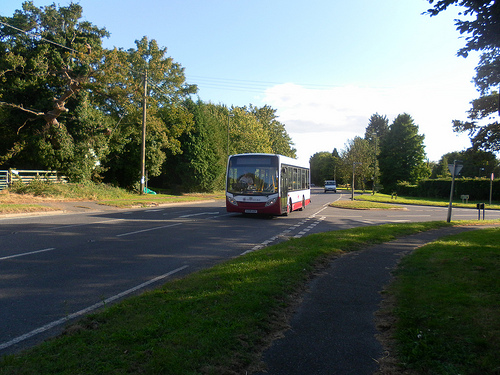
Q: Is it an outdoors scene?
A: Yes, it is outdoors.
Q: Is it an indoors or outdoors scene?
A: It is outdoors.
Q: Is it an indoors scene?
A: No, it is outdoors.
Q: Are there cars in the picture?
A: No, there are no cars.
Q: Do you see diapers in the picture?
A: No, there are no diapers.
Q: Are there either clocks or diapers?
A: No, there are no diapers or clocks.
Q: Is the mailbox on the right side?
A: Yes, the mailbox is on the right of the image.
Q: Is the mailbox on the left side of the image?
A: No, the mailbox is on the right of the image.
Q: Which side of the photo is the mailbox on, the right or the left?
A: The mailbox is on the right of the image.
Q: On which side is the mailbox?
A: The mailbox is on the right of the image.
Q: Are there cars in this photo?
A: No, there are no cars.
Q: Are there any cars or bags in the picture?
A: No, there are no cars or bags.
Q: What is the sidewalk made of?
A: The sidewalk is made of concrete.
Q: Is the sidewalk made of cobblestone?
A: No, the sidewalk is made of cement.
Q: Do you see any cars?
A: No, there are no cars.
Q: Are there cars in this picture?
A: No, there are no cars.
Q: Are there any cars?
A: No, there are no cars.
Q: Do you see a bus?
A: Yes, there is a bus.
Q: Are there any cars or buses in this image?
A: Yes, there is a bus.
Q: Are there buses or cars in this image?
A: Yes, there is a bus.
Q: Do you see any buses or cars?
A: Yes, there is a bus.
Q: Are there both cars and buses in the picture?
A: No, there is a bus but no cars.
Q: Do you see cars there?
A: No, there are no cars.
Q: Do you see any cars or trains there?
A: No, there are no cars or trains.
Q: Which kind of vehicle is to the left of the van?
A: The vehicle is a bus.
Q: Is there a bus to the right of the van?
A: No, the bus is to the left of the van.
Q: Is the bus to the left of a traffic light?
A: No, the bus is to the left of a van.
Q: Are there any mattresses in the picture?
A: No, there are no mattresses.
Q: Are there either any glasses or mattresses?
A: No, there are no mattresses or glasses.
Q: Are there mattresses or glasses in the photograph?
A: No, there are no mattresses or glasses.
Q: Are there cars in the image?
A: No, there are no cars.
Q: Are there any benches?
A: No, there are no benches.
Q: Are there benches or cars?
A: No, there are no benches or cars.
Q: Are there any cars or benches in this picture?
A: No, there are no benches or cars.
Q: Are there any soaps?
A: No, there are no soaps.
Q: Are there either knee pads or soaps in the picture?
A: No, there are no soaps or knee pads.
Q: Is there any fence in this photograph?
A: Yes, there is a fence.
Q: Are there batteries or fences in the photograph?
A: Yes, there is a fence.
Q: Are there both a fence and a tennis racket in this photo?
A: No, there is a fence but no rackets.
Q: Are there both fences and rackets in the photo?
A: No, there is a fence but no rackets.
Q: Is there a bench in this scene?
A: No, there are no benches.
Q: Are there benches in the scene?
A: No, there are no benches.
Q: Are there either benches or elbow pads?
A: No, there are no benches or elbow pads.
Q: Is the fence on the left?
A: Yes, the fence is on the left of the image.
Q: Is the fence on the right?
A: No, the fence is on the left of the image.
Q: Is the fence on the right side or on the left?
A: The fence is on the left of the image.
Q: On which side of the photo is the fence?
A: The fence is on the left of the image.